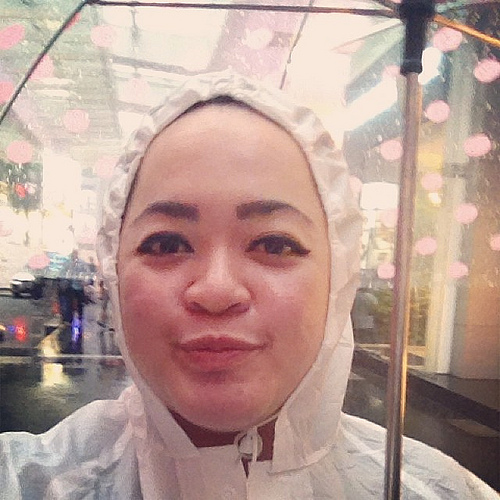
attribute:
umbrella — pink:
[43, 29, 494, 323]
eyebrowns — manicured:
[129, 183, 319, 232]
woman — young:
[60, 55, 408, 474]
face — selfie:
[131, 163, 322, 364]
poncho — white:
[26, 345, 448, 498]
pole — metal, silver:
[400, 65, 421, 365]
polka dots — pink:
[425, 100, 488, 163]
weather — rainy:
[29, 15, 463, 130]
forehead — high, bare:
[168, 112, 279, 179]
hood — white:
[72, 358, 361, 487]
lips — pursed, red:
[166, 324, 274, 368]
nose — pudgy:
[176, 267, 263, 318]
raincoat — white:
[30, 417, 452, 497]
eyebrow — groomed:
[233, 182, 311, 233]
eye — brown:
[129, 227, 213, 274]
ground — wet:
[37, 311, 123, 380]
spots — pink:
[19, 109, 110, 182]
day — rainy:
[35, 9, 489, 89]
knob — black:
[391, 2, 431, 76]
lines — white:
[34, 342, 125, 376]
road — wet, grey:
[63, 292, 125, 411]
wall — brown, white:
[454, 162, 495, 380]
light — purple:
[36, 61, 112, 108]